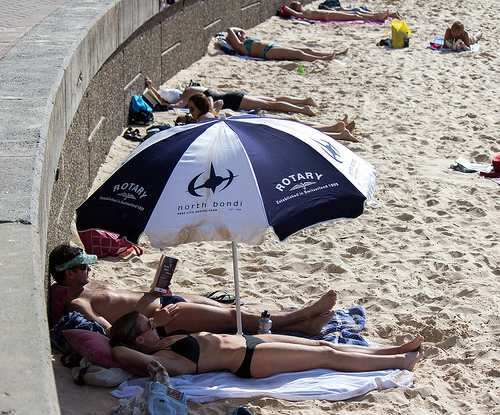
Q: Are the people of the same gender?
A: No, they are both male and female.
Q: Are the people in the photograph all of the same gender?
A: No, they are both male and female.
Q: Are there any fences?
A: No, there are no fences.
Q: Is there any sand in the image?
A: Yes, there is sand.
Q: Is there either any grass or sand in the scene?
A: Yes, there is sand.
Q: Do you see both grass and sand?
A: No, there is sand but no grass.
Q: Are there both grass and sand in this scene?
A: No, there is sand but no grass.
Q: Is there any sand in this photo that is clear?
A: Yes, there is clear sand.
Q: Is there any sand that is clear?
A: Yes, there is sand that is clear.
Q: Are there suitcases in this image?
A: No, there are no suitcases.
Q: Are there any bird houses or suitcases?
A: No, there are no suitcases or bird houses.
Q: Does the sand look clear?
A: Yes, the sand is clear.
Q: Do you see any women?
A: Yes, there is a woman.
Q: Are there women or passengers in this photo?
A: Yes, there is a woman.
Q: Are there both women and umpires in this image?
A: No, there is a woman but no umpires.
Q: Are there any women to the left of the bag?
A: Yes, there is a woman to the left of the bag.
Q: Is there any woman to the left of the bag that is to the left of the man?
A: Yes, there is a woman to the left of the bag.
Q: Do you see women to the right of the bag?
A: No, the woman is to the left of the bag.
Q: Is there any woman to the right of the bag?
A: No, the woman is to the left of the bag.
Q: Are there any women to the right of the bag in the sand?
A: No, the woman is to the left of the bag.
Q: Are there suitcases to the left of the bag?
A: No, there is a woman to the left of the bag.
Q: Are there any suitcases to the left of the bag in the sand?
A: No, there is a woman to the left of the bag.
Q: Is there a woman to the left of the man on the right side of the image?
A: Yes, there is a woman to the left of the man.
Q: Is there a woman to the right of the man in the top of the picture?
A: No, the woman is to the left of the man.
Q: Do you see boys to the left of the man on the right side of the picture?
A: No, there is a woman to the left of the man.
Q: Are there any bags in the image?
A: Yes, there is a bag.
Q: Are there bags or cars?
A: Yes, there is a bag.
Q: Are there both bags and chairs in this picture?
A: Yes, there are both a bag and a chair.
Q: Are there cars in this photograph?
A: No, there are no cars.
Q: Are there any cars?
A: No, there are no cars.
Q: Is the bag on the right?
A: Yes, the bag is on the right of the image.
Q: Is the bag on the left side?
A: No, the bag is on the right of the image.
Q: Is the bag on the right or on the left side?
A: The bag is on the right of the image.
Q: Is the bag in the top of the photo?
A: Yes, the bag is in the top of the image.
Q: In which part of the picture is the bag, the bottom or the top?
A: The bag is in the top of the image.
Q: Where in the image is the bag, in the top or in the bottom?
A: The bag is in the top of the image.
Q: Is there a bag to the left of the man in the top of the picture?
A: Yes, there is a bag to the left of the man.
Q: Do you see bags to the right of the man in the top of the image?
A: No, the bag is to the left of the man.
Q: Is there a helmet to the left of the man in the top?
A: No, there is a bag to the left of the man.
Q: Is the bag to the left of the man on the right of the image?
A: Yes, the bag is to the left of the man.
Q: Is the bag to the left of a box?
A: No, the bag is to the left of the man.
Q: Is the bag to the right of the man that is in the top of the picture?
A: No, the bag is to the left of the man.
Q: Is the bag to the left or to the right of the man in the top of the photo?
A: The bag is to the left of the man.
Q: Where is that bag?
A: The bag is in the sand.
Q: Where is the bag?
A: The bag is in the sand.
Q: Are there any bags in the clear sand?
A: Yes, there is a bag in the sand.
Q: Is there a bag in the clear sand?
A: Yes, there is a bag in the sand.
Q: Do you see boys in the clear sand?
A: No, there is a bag in the sand.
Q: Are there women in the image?
A: Yes, there is a woman.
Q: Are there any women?
A: Yes, there is a woman.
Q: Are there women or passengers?
A: Yes, there is a woman.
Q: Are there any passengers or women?
A: Yes, there is a woman.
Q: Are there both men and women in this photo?
A: Yes, there are both a woman and a man.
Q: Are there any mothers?
A: No, there are no mothers.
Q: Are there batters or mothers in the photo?
A: No, there are no mothers or batters.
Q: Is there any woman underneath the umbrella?
A: Yes, there is a woman underneath the umbrella.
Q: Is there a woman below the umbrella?
A: Yes, there is a woman below the umbrella.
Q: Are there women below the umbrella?
A: Yes, there is a woman below the umbrella.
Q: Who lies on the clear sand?
A: The woman lies on the sand.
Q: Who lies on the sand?
A: The woman lies on the sand.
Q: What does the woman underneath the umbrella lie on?
A: The woman lies on the sand.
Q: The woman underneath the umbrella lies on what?
A: The woman lies on the sand.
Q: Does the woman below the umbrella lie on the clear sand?
A: Yes, the woman lies on the sand.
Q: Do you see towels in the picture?
A: Yes, there is a towel.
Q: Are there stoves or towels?
A: Yes, there is a towel.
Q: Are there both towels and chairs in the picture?
A: Yes, there are both a towel and a chair.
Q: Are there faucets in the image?
A: No, there are no faucets.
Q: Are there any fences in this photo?
A: No, there are no fences.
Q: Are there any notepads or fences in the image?
A: No, there are no fences or notepads.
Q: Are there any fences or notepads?
A: No, there are no fences or notepads.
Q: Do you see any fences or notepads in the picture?
A: No, there are no fences or notepads.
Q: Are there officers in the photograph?
A: No, there are no officers.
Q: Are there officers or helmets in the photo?
A: No, there are no officers or helmets.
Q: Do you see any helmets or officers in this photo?
A: No, there are no officers or helmets.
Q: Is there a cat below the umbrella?
A: No, there is a man below the umbrella.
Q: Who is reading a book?
A: The man is reading a book.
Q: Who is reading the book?
A: The man is reading a book.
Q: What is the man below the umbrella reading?
A: The man is reading a book.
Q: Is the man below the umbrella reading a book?
A: Yes, the man is reading a book.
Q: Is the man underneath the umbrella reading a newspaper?
A: No, the man is reading a book.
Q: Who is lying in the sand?
A: The man is lying in the sand.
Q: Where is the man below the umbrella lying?
A: The man is lying in the sand.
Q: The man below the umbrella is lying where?
A: The man is lying in the sand.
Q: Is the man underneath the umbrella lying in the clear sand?
A: Yes, the man is lying in the sand.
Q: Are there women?
A: Yes, there is a woman.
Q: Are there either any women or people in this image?
A: Yes, there is a woman.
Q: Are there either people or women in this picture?
A: Yes, there is a woman.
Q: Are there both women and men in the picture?
A: Yes, there are both a woman and a man.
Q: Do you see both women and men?
A: Yes, there are both a woman and a man.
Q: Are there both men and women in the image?
A: Yes, there are both a woman and a man.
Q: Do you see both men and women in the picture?
A: Yes, there are both a woman and a man.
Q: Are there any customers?
A: No, there are no customers.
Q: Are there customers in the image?
A: No, there are no customers.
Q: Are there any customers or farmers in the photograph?
A: No, there are no customers or farmers.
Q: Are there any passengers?
A: No, there are no passengers.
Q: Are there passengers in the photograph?
A: No, there are no passengers.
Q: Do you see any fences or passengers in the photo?
A: No, there are no passengers or fences.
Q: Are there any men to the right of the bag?
A: Yes, there is a man to the right of the bag.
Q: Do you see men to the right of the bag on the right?
A: Yes, there is a man to the right of the bag.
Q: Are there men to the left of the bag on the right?
A: No, the man is to the right of the bag.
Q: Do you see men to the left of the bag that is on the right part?
A: No, the man is to the right of the bag.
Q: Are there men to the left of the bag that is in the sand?
A: No, the man is to the right of the bag.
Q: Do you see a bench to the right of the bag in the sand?
A: No, there is a man to the right of the bag.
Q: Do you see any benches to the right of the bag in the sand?
A: No, there is a man to the right of the bag.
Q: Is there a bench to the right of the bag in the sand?
A: No, there is a man to the right of the bag.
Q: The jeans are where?
A: The jeans are on the sand.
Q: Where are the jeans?
A: The jeans are on the sand.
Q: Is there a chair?
A: Yes, there is a chair.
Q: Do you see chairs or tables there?
A: Yes, there is a chair.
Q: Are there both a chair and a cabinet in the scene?
A: No, there is a chair but no cabinets.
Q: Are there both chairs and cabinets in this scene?
A: No, there is a chair but no cabinets.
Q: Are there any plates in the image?
A: No, there are no plates.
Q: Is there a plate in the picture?
A: No, there are no plates.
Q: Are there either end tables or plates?
A: No, there are no plates or end tables.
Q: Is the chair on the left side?
A: Yes, the chair is on the left of the image.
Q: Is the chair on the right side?
A: No, the chair is on the left of the image.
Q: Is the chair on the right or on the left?
A: The chair is on the left of the image.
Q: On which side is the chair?
A: The chair is on the left of the image.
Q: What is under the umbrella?
A: The chair is under the umbrella.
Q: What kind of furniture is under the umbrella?
A: The piece of furniture is a chair.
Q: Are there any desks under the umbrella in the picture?
A: No, there is a chair under the umbrella.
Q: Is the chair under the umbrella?
A: Yes, the chair is under the umbrella.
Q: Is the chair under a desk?
A: No, the chair is under the umbrella.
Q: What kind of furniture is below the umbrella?
A: The piece of furniture is a chair.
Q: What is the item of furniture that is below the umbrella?
A: The piece of furniture is a chair.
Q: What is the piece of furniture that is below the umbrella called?
A: The piece of furniture is a chair.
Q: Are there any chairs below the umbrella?
A: Yes, there is a chair below the umbrella.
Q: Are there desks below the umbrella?
A: No, there is a chair below the umbrella.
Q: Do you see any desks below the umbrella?
A: No, there is a chair below the umbrella.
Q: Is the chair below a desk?
A: No, the chair is below the umbrella.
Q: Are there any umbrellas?
A: Yes, there is an umbrella.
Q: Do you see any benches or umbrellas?
A: Yes, there is an umbrella.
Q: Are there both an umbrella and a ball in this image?
A: No, there is an umbrella but no balls.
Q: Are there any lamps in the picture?
A: No, there are no lamps.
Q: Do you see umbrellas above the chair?
A: Yes, there is an umbrella above the chair.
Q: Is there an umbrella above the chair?
A: Yes, there is an umbrella above the chair.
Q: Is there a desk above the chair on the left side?
A: No, there is an umbrella above the chair.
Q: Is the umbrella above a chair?
A: Yes, the umbrella is above a chair.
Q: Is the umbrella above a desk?
A: No, the umbrella is above a chair.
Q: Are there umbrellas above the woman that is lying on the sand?
A: Yes, there is an umbrella above the woman.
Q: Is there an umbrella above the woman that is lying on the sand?
A: Yes, there is an umbrella above the woman.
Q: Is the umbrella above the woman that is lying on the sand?
A: Yes, the umbrella is above the woman.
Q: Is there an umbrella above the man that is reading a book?
A: Yes, there is an umbrella above the man.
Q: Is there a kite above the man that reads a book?
A: No, there is an umbrella above the man.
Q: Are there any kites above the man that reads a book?
A: No, there is an umbrella above the man.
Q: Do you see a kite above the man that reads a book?
A: No, there is an umbrella above the man.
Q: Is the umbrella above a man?
A: Yes, the umbrella is above a man.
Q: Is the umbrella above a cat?
A: No, the umbrella is above a man.